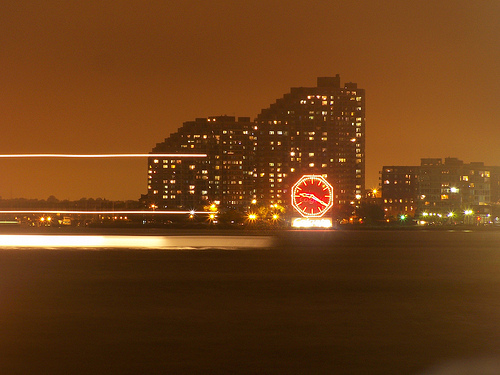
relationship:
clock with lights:
[289, 173, 336, 235] [292, 214, 331, 224]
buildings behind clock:
[150, 92, 395, 167] [289, 163, 342, 227]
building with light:
[378, 156, 498, 228] [384, 180, 388, 182]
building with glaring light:
[378, 156, 498, 228] [400, 215, 406, 220]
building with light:
[378, 156, 498, 228] [421, 195, 425, 199]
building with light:
[378, 156, 498, 228] [441, 195, 448, 200]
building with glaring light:
[378, 156, 498, 228] [464, 209, 473, 215]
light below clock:
[285, 216, 332, 229] [276, 164, 353, 226]